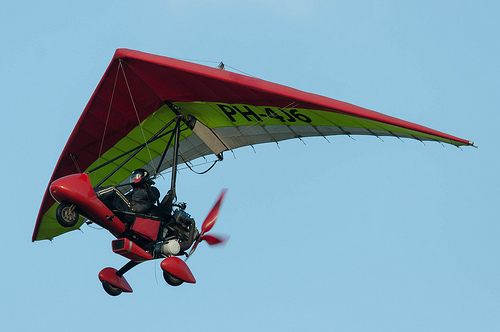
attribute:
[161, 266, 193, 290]
tire — black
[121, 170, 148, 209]
jacket — black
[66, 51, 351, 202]
plane — red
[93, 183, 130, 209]
pants — black, white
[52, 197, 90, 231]
wheel — black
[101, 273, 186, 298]
wheels — small, black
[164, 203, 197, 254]
engine — ultralight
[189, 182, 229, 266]
propeller — red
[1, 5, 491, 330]
sky — blue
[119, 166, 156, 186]
helmet — black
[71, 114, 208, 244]
person — hang gliding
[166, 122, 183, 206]
support pole — black, metal